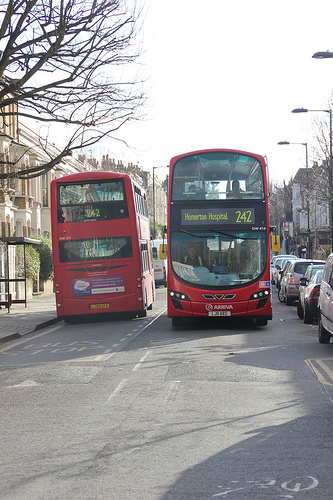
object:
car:
[315, 253, 331, 343]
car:
[277, 258, 326, 305]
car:
[272, 254, 296, 287]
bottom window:
[58, 235, 133, 261]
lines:
[107, 347, 151, 407]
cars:
[297, 261, 332, 324]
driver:
[180, 237, 205, 269]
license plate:
[90, 303, 110, 309]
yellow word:
[206, 211, 229, 220]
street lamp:
[278, 140, 306, 145]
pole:
[303, 141, 311, 254]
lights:
[166, 287, 193, 301]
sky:
[0, 0, 330, 179]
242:
[233, 208, 253, 225]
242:
[87, 209, 99, 217]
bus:
[49, 170, 155, 324]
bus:
[166, 147, 271, 328]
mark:
[211, 473, 320, 499]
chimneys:
[80, 150, 152, 177]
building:
[0, 81, 166, 307]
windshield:
[168, 230, 266, 287]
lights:
[277, 49, 333, 205]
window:
[173, 153, 265, 199]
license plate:
[208, 309, 231, 316]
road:
[2, 288, 333, 499]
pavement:
[2, 277, 332, 499]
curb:
[2, 317, 78, 363]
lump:
[167, 289, 191, 301]